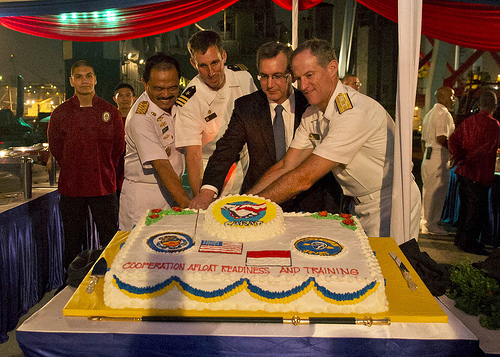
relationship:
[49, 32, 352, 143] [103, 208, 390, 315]
military members in front of cake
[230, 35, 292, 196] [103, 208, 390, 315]
men are cutting cake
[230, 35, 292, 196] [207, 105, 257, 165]
men are in uniform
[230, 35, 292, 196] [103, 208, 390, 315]
men cutting cake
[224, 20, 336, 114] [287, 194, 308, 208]
man wearing suit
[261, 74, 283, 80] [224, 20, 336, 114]
glasses on man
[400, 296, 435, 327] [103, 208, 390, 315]
platter under cake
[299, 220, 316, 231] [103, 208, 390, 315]
frosting on cake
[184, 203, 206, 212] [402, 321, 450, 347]
knife on table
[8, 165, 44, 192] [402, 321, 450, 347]
food on table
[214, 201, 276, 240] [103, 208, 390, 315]
emblems on top of cake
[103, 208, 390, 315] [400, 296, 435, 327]
cake on top of platter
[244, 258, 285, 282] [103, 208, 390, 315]
decoration on side of cake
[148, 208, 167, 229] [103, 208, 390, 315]
flowers on top of cake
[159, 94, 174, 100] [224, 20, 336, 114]
mustache on man